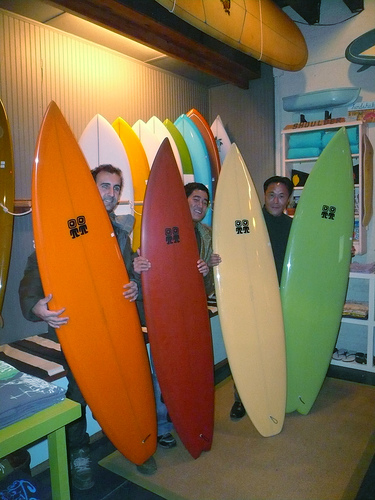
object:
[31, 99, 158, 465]
surfboard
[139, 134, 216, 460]
surfboard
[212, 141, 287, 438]
surfboard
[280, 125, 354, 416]
surfboard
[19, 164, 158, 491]
person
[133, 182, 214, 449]
person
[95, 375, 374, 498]
mat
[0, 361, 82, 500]
table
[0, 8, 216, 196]
wall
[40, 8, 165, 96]
light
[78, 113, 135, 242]
surfboard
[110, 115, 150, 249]
surfboard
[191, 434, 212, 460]
tail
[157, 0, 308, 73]
surfboard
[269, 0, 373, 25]
ceiling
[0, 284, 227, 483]
cabinet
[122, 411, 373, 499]
floor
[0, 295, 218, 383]
cushion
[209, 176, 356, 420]
person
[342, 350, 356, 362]
shoe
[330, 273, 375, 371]
shelf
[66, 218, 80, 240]
caricature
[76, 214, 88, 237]
caricature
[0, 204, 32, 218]
cord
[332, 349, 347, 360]
shoe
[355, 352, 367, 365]
shoe